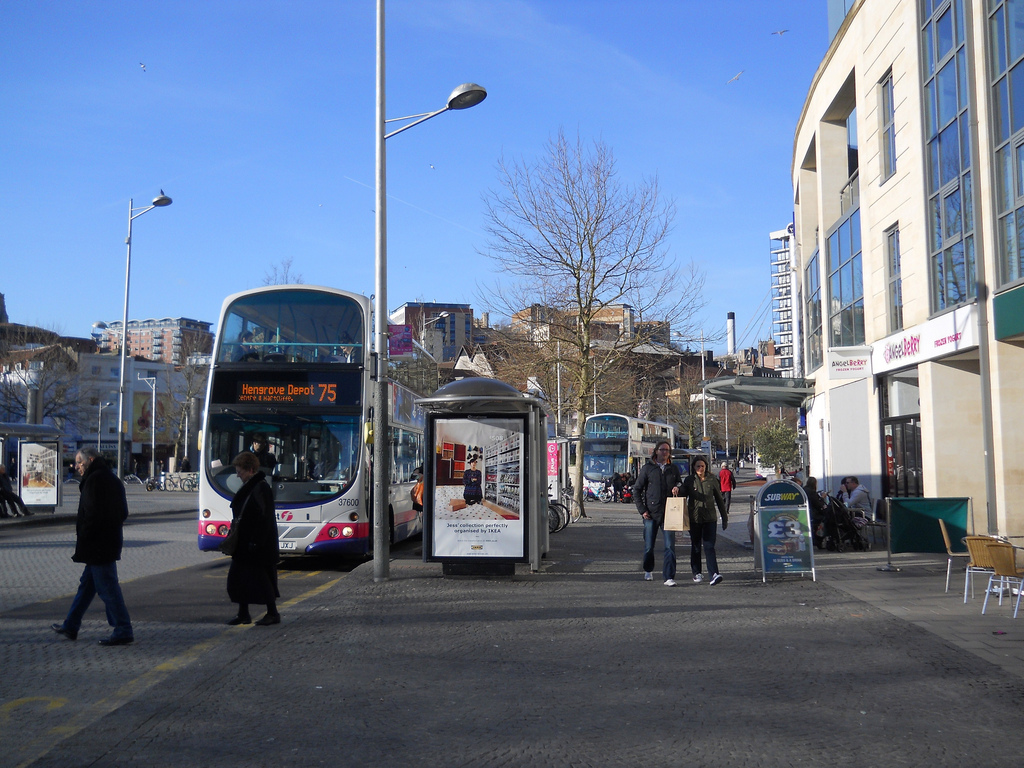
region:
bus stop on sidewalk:
[415, 371, 548, 572]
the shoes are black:
[228, 615, 280, 626]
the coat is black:
[228, 470, 277, 603]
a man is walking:
[55, 448, 136, 645]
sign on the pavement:
[753, 479, 817, 582]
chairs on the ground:
[937, 521, 1021, 614]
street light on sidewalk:
[392, 1, 485, 583]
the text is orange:
[235, 384, 338, 405]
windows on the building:
[803, 0, 1022, 370]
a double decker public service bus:
[193, 283, 443, 568]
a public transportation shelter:
[417, 378, 553, 582]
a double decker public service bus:
[578, 410, 676, 496]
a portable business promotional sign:
[748, 478, 824, 586]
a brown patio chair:
[936, 522, 968, 592]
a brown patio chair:
[960, 530, 1006, 598]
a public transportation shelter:
[2, 427, 66, 522]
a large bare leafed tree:
[479, 127, 724, 542]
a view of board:
[420, 443, 611, 641]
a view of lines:
[120, 597, 302, 712]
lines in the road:
[125, 568, 284, 671]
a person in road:
[190, 418, 304, 638]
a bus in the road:
[180, 279, 450, 625]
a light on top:
[397, 23, 538, 194]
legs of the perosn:
[32, 546, 207, 652]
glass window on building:
[989, 12, 1008, 88]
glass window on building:
[1005, 1, 1019, 66]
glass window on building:
[918, 64, 938, 142]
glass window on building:
[961, 233, 978, 301]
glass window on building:
[942, 245, 968, 309]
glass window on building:
[879, 72, 890, 177]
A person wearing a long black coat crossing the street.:
[208, 440, 317, 630]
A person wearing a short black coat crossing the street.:
[40, 429, 152, 649]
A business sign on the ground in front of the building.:
[748, 477, 818, 588]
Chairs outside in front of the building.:
[931, 499, 1020, 632]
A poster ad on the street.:
[413, 412, 534, 565]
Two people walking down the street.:
[611, 431, 726, 597]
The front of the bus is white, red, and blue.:
[172, 289, 373, 568]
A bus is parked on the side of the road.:
[564, 381, 676, 506]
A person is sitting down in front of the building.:
[786, 468, 831, 545]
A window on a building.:
[876, 234, 903, 270]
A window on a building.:
[879, 76, 902, 166]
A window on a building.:
[822, 234, 841, 270]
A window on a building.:
[836, 216, 853, 262]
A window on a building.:
[819, 269, 839, 311]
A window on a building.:
[833, 261, 853, 307]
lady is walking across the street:
[220, 452, 281, 629]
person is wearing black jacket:
[48, 444, 134, 650]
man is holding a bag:
[630, 435, 687, 588]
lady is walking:
[671, 444, 730, 582]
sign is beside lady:
[750, 479, 820, 579]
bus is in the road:
[197, 280, 432, 560]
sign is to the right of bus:
[415, 373, 551, 561]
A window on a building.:
[872, 76, 898, 176]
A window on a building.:
[941, 118, 964, 179]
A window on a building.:
[944, 190, 974, 242]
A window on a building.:
[935, 241, 977, 308]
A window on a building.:
[885, 235, 918, 324]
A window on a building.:
[797, 254, 830, 352]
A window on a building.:
[876, 73, 906, 172]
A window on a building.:
[152, 333, 162, 338]